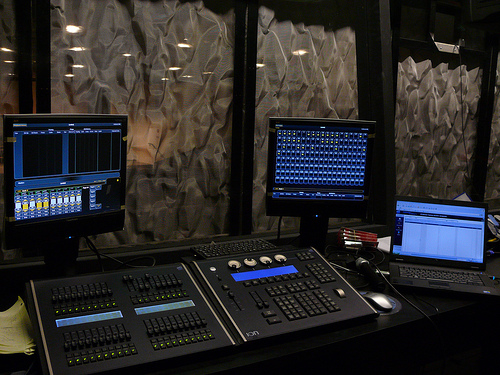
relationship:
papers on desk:
[3, 296, 29, 354] [6, 254, 441, 355]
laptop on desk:
[381, 179, 493, 301] [11, 209, 484, 359]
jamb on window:
[233, 2, 256, 234] [49, 4, 234, 255]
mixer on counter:
[20, 242, 379, 372] [0, 213, 498, 372]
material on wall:
[48, 0, 236, 247] [1, 1, 499, 264]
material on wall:
[255, 5, 358, 236] [1, 1, 499, 264]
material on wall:
[391, 47, 481, 227] [1, 1, 499, 264]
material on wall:
[483, 51, 499, 213] [1, 1, 499, 264]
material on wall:
[1, 2, 21, 144] [1, 1, 499, 264]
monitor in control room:
[0, 113, 127, 262] [7, 8, 495, 368]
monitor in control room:
[263, 111, 380, 216] [7, 8, 495, 368]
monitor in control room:
[387, 190, 491, 266] [7, 8, 495, 368]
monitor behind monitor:
[263, 111, 380, 216] [375, 191, 479, 301]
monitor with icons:
[0, 113, 127, 278] [9, 174, 119, 218]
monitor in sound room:
[33, 261, 243, 370] [2, 2, 495, 373]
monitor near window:
[263, 111, 380, 216] [253, 10, 368, 236]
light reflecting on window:
[160, 38, 216, 84] [54, 0, 234, 235]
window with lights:
[39, 4, 251, 246] [1, 19, 314, 87]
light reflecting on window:
[62, 14, 321, 86] [386, 30, 486, 236]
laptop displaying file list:
[385, 194, 492, 300] [406, 214, 484, 261]